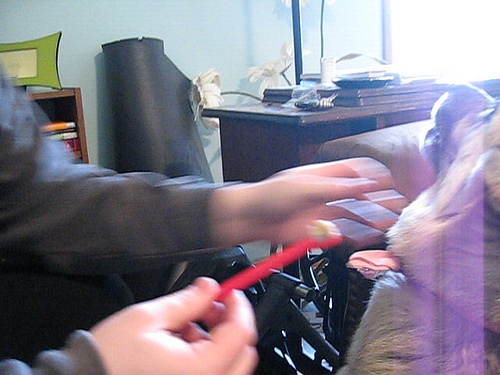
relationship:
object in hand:
[235, 249, 337, 291] [94, 293, 261, 369]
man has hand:
[0, 48, 406, 364] [94, 293, 261, 369]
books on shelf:
[53, 125, 88, 149] [10, 96, 81, 111]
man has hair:
[0, 48, 406, 364] [2, 120, 24, 173]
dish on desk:
[328, 60, 378, 84] [204, 91, 331, 135]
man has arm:
[0, 48, 406, 364] [8, 135, 241, 263]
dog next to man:
[422, 102, 475, 351] [0, 48, 406, 364]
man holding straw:
[8, 197, 156, 291] [217, 239, 328, 312]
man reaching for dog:
[8, 197, 156, 291] [422, 102, 475, 351]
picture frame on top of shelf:
[4, 26, 71, 88] [10, 96, 81, 111]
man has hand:
[8, 197, 156, 291] [94, 293, 261, 369]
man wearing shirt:
[8, 197, 156, 291] [19, 338, 104, 371]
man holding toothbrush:
[8, 197, 156, 291] [306, 211, 347, 269]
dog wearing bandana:
[422, 102, 475, 351] [329, 240, 453, 300]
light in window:
[308, 12, 443, 58] [357, 1, 476, 71]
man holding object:
[0, 48, 406, 364] [235, 249, 337, 291]